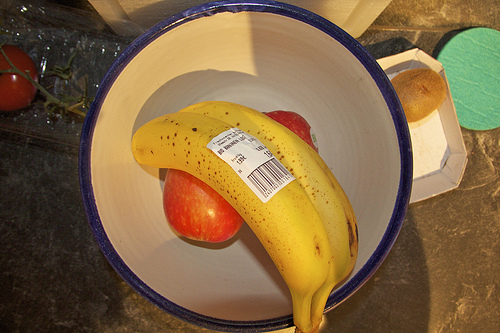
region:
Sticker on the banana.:
[200, 117, 303, 204]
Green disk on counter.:
[442, 29, 498, 138]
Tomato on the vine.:
[1, 43, 44, 118]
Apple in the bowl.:
[157, 154, 248, 251]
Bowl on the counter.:
[75, 2, 417, 331]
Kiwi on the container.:
[387, 62, 452, 125]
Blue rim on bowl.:
[72, 3, 417, 330]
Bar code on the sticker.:
[241, 154, 298, 201]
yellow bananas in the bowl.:
[132, 95, 365, 332]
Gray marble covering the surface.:
[1, 3, 497, 330]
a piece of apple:
[140, 159, 255, 278]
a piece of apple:
[150, 167, 228, 238]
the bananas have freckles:
[131, 95, 371, 302]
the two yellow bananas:
[125, 85, 362, 326]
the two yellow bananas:
[123, 90, 390, 327]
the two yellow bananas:
[149, 67, 354, 327]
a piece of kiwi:
[385, 57, 452, 136]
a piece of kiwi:
[372, 52, 448, 133]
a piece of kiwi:
[377, 54, 474, 147]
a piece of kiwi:
[378, 62, 453, 124]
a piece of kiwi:
[385, 52, 450, 116]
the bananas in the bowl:
[136, 83, 367, 331]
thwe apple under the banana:
[151, 171, 239, 254]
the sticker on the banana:
[207, 121, 295, 203]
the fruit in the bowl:
[71, 3, 413, 330]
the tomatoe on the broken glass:
[2, 46, 57, 122]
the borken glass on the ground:
[37, 30, 100, 93]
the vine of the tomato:
[40, 75, 85, 139]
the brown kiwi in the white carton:
[396, 60, 447, 120]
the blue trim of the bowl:
[94, 249, 255, 327]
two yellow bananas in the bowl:
[131, 100, 360, 332]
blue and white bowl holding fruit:
[82, 3, 412, 328]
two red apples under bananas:
[165, 108, 320, 247]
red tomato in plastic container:
[0, 43, 40, 115]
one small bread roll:
[385, 65, 449, 126]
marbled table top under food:
[4, 0, 496, 332]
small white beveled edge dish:
[369, 47, 469, 203]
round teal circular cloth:
[434, 23, 499, 131]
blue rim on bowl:
[77, 1, 414, 331]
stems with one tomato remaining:
[2, 41, 87, 118]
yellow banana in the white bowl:
[124, 114, 332, 330]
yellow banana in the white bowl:
[185, 98, 359, 331]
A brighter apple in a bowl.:
[161, 168, 244, 245]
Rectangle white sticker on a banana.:
[206, 126, 296, 203]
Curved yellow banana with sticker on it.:
[131, 111, 333, 332]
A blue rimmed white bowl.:
[76, 1, 413, 331]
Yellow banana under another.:
[179, 99, 359, 293]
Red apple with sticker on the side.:
[262, 109, 319, 154]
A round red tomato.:
[1, 44, 38, 111]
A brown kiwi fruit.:
[390, 66, 445, 125]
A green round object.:
[436, 27, 498, 130]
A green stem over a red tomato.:
[1, 50, 88, 118]